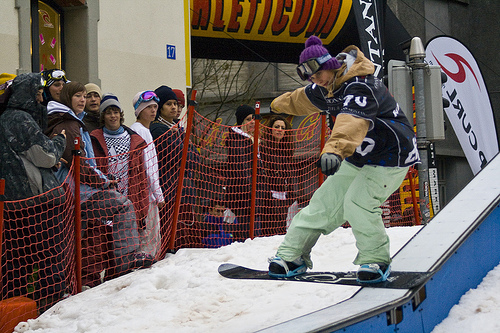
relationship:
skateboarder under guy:
[218, 262, 433, 291] [267, 36, 423, 282]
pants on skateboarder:
[268, 156, 392, 270] [218, 262, 433, 291]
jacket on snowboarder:
[269, 45, 419, 165] [247, 38, 407, 279]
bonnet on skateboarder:
[297, 36, 341, 82] [218, 262, 433, 291]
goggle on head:
[297, 55, 333, 81] [296, 32, 341, 89]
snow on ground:
[12, 227, 498, 332] [5, 221, 497, 331]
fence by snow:
[7, 90, 418, 333] [12, 227, 498, 332]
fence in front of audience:
[7, 90, 418, 300] [2, 62, 299, 314]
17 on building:
[161, 45, 178, 62] [3, 0, 194, 133]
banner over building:
[190, 2, 356, 44] [1, 2, 498, 209]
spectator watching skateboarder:
[15, 68, 53, 191] [285, 35, 409, 330]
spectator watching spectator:
[45, 67, 59, 96] [15, 68, 53, 191]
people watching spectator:
[92, 93, 156, 272] [15, 68, 53, 191]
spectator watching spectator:
[80, 86, 94, 106] [15, 68, 53, 191]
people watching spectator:
[129, 89, 167, 259] [15, 68, 53, 191]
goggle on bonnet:
[297, 55, 333, 81] [291, 32, 340, 82]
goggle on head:
[297, 60, 324, 79] [295, 41, 336, 86]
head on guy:
[295, 41, 336, 86] [287, 45, 403, 282]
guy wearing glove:
[267, 36, 423, 282] [315, 152, 341, 175]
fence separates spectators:
[7, 90, 418, 333] [17, 63, 292, 233]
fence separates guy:
[7, 90, 418, 333] [267, 36, 423, 282]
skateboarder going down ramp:
[218, 262, 433, 291] [31, 92, 484, 329]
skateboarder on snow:
[218, 262, 433, 291] [46, 206, 411, 323]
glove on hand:
[314, 151, 354, 178] [314, 148, 342, 172]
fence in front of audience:
[7, 90, 418, 333] [2, 62, 299, 314]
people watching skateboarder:
[92, 93, 149, 228] [218, 262, 433, 291]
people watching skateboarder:
[129, 89, 167, 259] [218, 262, 433, 291]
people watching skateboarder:
[149, 87, 192, 252] [218, 262, 433, 291]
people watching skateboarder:
[228, 103, 265, 233] [218, 262, 433, 291]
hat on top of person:
[236, 104, 253, 129] [232, 96, 262, 243]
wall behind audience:
[7, 9, 253, 228] [10, 62, 286, 231]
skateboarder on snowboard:
[218, 262, 433, 291] [207, 250, 433, 290]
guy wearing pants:
[267, 36, 423, 282] [271, 166, 411, 266]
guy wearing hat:
[267, 36, 423, 282] [299, 34, 339, 72]